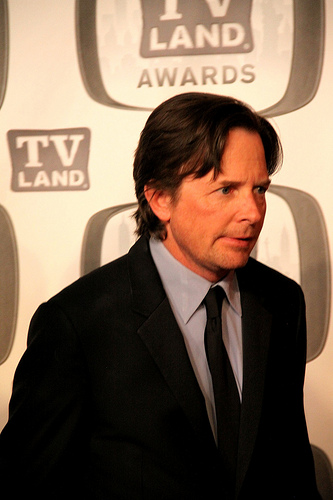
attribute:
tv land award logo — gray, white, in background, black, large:
[6, 123, 95, 194]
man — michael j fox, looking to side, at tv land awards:
[5, 88, 315, 500]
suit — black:
[4, 235, 315, 500]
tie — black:
[200, 279, 243, 465]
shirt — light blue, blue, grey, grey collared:
[148, 233, 248, 459]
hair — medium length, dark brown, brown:
[129, 90, 284, 244]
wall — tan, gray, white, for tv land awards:
[3, 3, 332, 499]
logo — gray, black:
[133, 1, 267, 91]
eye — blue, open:
[221, 186, 233, 195]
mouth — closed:
[223, 232, 255, 247]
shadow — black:
[212, 279, 243, 337]